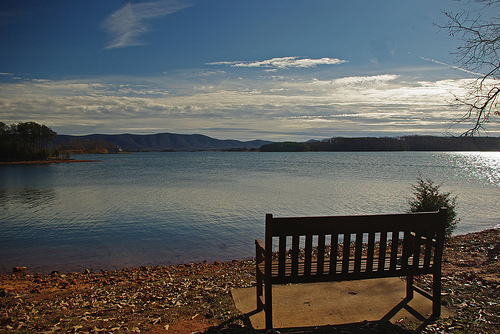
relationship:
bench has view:
[234, 201, 457, 333] [2, 73, 498, 277]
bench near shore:
[234, 201, 457, 333] [4, 222, 500, 305]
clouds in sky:
[3, 7, 497, 147] [6, 1, 496, 148]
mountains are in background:
[0, 114, 499, 159] [2, 2, 500, 159]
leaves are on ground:
[9, 257, 497, 331] [2, 227, 499, 333]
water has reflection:
[1, 145, 495, 308] [9, 171, 462, 233]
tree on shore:
[401, 168, 467, 242] [4, 222, 500, 305]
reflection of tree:
[460, 215, 497, 234] [401, 168, 467, 242]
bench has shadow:
[234, 201, 457, 333] [195, 291, 444, 333]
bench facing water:
[234, 201, 457, 333] [1, 145, 495, 308]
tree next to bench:
[401, 168, 467, 242] [234, 201, 457, 333]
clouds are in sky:
[3, 7, 497, 147] [6, 1, 496, 148]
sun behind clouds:
[419, 64, 492, 123] [3, 7, 497, 147]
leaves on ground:
[9, 257, 497, 331] [2, 227, 499, 333]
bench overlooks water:
[234, 201, 457, 333] [1, 145, 495, 308]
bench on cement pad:
[234, 201, 457, 333] [222, 271, 458, 330]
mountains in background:
[0, 114, 499, 159] [2, 2, 500, 159]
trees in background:
[2, 117, 59, 139] [2, 2, 500, 159]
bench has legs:
[234, 201, 457, 333] [244, 277, 448, 331]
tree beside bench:
[401, 168, 467, 242] [234, 201, 457, 333]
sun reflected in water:
[419, 64, 492, 123] [1, 145, 495, 308]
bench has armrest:
[234, 201, 457, 333] [250, 234, 267, 269]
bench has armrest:
[234, 201, 457, 333] [400, 226, 438, 267]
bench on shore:
[234, 201, 457, 333] [4, 222, 500, 305]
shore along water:
[4, 222, 500, 305] [1, 145, 495, 308]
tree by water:
[401, 168, 467, 242] [1, 145, 495, 308]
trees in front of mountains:
[2, 117, 59, 139] [0, 114, 499, 159]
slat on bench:
[276, 234, 291, 279] [234, 201, 457, 333]